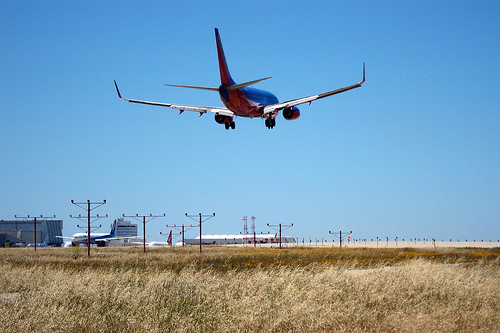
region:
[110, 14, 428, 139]
the plane in the sky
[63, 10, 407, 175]
the plane is flying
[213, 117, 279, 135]
the landing gear of the plane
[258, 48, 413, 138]
the wing of the plane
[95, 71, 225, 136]
the wing of the plane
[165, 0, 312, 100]
the tail of the plane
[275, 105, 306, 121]
the engine under the plane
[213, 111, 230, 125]
the engine under the plane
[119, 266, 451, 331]
the grass below the plane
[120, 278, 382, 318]
the tall grass is dry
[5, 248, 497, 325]
GRASSY AREA IS OF TAN COLOR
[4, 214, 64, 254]
BUILDING IS LOCATED AT AN AIRPORT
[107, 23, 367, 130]
PLANE IS COMING IN FOR A LANDING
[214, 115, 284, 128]
LANDING GEAR BELOW THE PLANE IS DOWN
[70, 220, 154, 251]
PLANE IS OF A WHITE AND BLUE COLOR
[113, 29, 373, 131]
PLANE IN AIR IS BLUE, RED AND WHITE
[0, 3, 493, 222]
SKY IS A BRIGHT BLUE IN COLOR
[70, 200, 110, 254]
POLE HAS FOUR CROSS BEAMS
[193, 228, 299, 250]
BUILDING WHERE PLANES ARE PARKED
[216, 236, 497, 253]
FENCE IS WHITE IN COLOR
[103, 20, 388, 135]
An airplane landing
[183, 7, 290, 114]
A dark blue airplane body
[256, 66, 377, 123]
Right blue and white wing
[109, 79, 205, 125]
Left blue and white wing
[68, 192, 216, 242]
A row of utility poles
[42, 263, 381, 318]
Dried looking grass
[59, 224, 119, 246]
White plane on ground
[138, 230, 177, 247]
Planes in the background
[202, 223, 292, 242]
Long white building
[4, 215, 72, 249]
A large gray building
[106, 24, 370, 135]
airplane landing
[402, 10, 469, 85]
white clouds in blue sky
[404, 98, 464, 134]
white clouds in blue sky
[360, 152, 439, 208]
white clouds in blue sky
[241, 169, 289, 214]
white clouds in blue sky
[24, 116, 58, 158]
white clouds in blue sky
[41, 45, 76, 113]
white clouds in blue sky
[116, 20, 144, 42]
white clouds in blue sky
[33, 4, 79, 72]
white clouds in blue sky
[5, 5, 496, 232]
The sky is clear blue.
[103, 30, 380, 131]
The plane is landing.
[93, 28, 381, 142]
The plane is blue and red.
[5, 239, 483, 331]
The grass is dying.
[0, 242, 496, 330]
The grass is brown.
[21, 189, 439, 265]
The light posts are tall.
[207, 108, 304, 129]
The wheels are down.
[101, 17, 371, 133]
The plane is in the air.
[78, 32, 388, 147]
The plane is flying.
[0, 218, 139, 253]
The buildings are in the background.